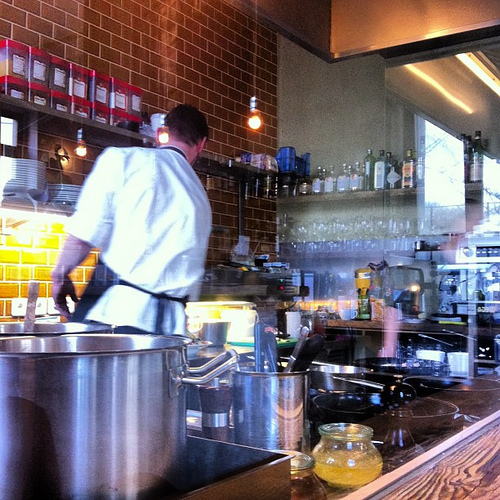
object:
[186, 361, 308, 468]
small container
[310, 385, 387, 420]
frying pan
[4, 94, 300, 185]
shelf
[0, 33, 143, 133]
spices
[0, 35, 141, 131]
lids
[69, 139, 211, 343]
tshirt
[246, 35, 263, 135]
light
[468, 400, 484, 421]
part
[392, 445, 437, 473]
edge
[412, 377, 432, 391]
part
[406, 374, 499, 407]
plate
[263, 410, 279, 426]
edge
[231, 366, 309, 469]
tin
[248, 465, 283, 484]
part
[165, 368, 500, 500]
table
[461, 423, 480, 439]
edge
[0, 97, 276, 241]
chef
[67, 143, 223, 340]
shirt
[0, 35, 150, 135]
containers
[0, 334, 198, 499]
pot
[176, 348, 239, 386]
handle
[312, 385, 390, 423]
pans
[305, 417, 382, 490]
container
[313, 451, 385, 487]
liquid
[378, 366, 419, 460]
grinder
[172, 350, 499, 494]
counter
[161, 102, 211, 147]
hair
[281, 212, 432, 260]
glasses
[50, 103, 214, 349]
man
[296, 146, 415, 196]
bottle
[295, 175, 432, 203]
shelf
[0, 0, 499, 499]
restaurant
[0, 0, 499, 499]
area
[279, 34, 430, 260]
wall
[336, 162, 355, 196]
jars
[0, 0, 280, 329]
wall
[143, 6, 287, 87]
bricks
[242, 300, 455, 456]
items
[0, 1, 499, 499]
kitchen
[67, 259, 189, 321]
apron